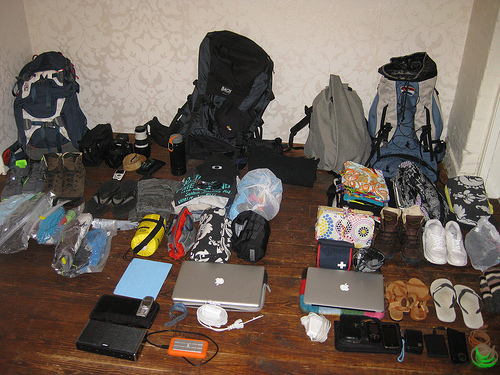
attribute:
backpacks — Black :
[21, 55, 454, 194]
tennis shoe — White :
[422, 220, 446, 267]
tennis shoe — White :
[448, 221, 468, 267]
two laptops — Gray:
[169, 251, 386, 324]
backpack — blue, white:
[21, 48, 81, 165]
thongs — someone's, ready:
[385, 253, 452, 325]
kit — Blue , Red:
[312, 236, 357, 271]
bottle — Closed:
[165, 130, 194, 176]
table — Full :
[21, 105, 498, 365]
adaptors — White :
[186, 293, 275, 341]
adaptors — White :
[287, 298, 349, 345]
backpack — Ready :
[294, 73, 376, 179]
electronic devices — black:
[332, 312, 406, 356]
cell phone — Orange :
[163, 335, 213, 357]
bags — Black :
[3, 187, 140, 278]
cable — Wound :
[194, 302, 268, 329]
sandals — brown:
[384, 268, 434, 329]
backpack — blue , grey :
[354, 35, 454, 202]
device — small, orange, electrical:
[154, 339, 214, 361]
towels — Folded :
[446, 171, 493, 226]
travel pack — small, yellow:
[113, 203, 187, 255]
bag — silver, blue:
[146, 29, 291, 157]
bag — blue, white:
[11, 46, 88, 158]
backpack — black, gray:
[161, 28, 279, 179]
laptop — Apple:
[172, 258, 267, 313]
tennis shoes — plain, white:
[361, 192, 483, 272]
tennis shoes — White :
[421, 218, 473, 266]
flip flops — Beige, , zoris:
[427, 274, 487, 331]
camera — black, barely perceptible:
[110, 132, 133, 164]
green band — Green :
[470, 345, 499, 370]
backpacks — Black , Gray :
[6, 50, 92, 162]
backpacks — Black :
[147, 19, 272, 158]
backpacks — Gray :
[298, 73, 374, 174]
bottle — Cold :
[167, 130, 185, 178]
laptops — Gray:
[175, 258, 386, 318]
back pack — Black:
[34, 43, 107, 173]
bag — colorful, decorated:
[316, 80, 392, 197]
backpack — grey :
[274, 68, 369, 187]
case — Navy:
[310, 237, 356, 270]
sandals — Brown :
[385, 275, 431, 321]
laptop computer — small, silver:
[297, 264, 388, 319]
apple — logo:
[213, 275, 225, 286]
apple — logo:
[340, 281, 350, 292]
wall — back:
[22, 3, 473, 145]